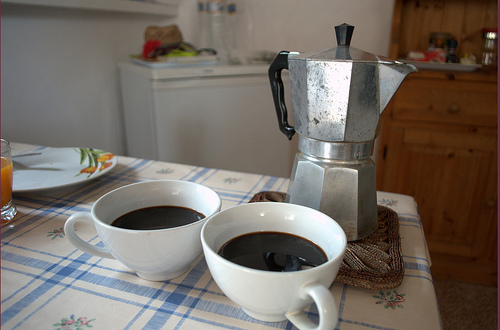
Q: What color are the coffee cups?
A: White.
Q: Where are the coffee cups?
A: On the table.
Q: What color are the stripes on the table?
A: Blue.